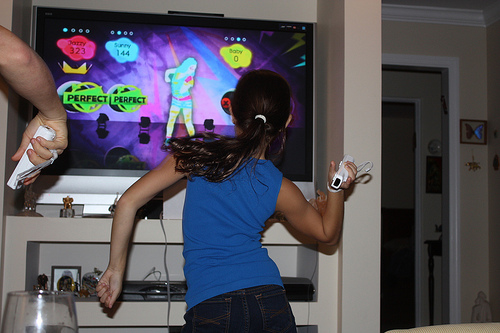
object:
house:
[1, 0, 500, 333]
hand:
[328, 161, 357, 191]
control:
[330, 154, 374, 191]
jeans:
[183, 284, 298, 332]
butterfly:
[465, 123, 483, 139]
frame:
[460, 119, 488, 145]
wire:
[159, 215, 170, 330]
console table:
[424, 233, 443, 326]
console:
[282, 277, 316, 301]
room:
[0, 0, 500, 333]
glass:
[1, 291, 78, 333]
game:
[35, 6, 314, 182]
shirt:
[181, 156, 285, 311]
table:
[424, 201, 448, 325]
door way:
[382, 53, 461, 330]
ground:
[425, 156, 443, 194]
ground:
[315, 136, 345, 159]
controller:
[7, 125, 56, 190]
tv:
[31, 5, 319, 184]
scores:
[66, 41, 132, 57]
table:
[0, 327, 169, 333]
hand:
[11, 111, 69, 185]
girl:
[94, 70, 356, 333]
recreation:
[93, 69, 358, 333]